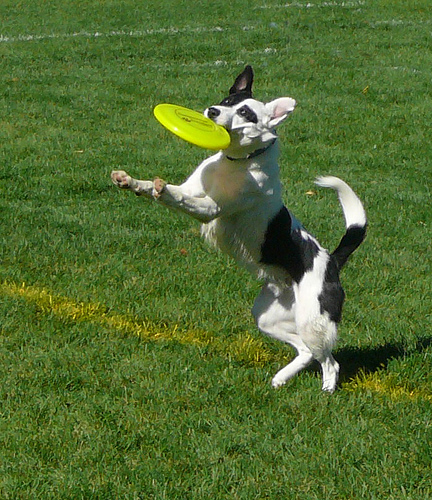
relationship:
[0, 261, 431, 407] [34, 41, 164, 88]
stripe painted on grass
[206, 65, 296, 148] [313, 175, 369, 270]
head similar to tail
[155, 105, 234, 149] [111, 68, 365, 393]
frisbee in dog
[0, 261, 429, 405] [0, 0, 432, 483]
stripe on grass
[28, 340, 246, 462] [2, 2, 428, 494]
grass covered field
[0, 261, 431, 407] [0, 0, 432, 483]
stripe in grass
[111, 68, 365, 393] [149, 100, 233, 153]
dog catching frisbee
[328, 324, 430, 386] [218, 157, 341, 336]
shadow from body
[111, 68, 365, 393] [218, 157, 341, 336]
dog has body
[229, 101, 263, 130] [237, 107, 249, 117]
patch around dog's eye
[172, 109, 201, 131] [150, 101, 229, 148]
logo on top of frisbee